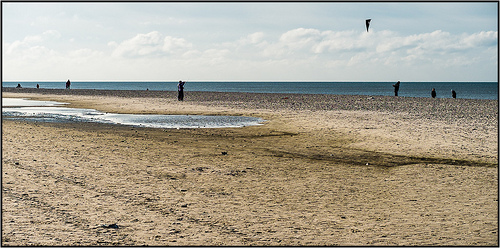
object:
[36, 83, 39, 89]
people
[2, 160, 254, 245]
tire tracks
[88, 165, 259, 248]
footprints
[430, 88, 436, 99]
people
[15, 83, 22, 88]
people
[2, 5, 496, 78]
clouds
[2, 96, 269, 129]
puddles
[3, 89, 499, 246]
sand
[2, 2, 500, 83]
sky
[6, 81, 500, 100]
water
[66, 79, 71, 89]
man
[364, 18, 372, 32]
kite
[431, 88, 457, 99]
bystanders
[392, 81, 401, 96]
kite flyers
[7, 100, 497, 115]
shore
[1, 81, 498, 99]
ocean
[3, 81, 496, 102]
shoreline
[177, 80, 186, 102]
man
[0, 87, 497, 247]
beach